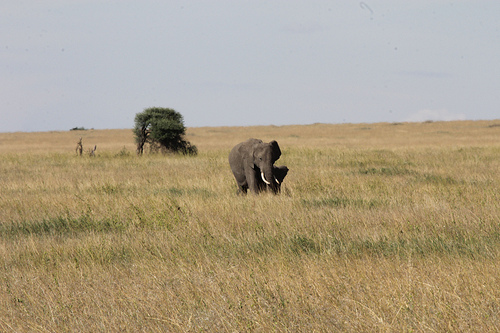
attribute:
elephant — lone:
[226, 138, 290, 195]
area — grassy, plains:
[3, 125, 484, 315]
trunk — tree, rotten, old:
[70, 132, 85, 154]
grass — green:
[6, 215, 484, 270]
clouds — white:
[34, 30, 90, 77]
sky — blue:
[9, 3, 484, 122]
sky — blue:
[51, 15, 484, 121]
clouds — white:
[408, 26, 467, 99]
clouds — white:
[135, 39, 210, 103]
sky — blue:
[48, 9, 405, 104]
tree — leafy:
[134, 104, 200, 158]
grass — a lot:
[25, 199, 484, 305]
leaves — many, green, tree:
[141, 115, 181, 145]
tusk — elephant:
[258, 166, 270, 186]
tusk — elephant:
[273, 164, 283, 184]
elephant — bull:
[224, 129, 285, 199]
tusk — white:
[258, 168, 269, 187]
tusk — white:
[270, 165, 280, 185]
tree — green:
[120, 100, 195, 169]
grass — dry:
[18, 125, 458, 313]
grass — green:
[2, 210, 127, 240]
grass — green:
[249, 230, 498, 260]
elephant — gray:
[230, 139, 284, 195]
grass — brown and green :
[7, 117, 498, 331]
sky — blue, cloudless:
[1, 1, 497, 138]